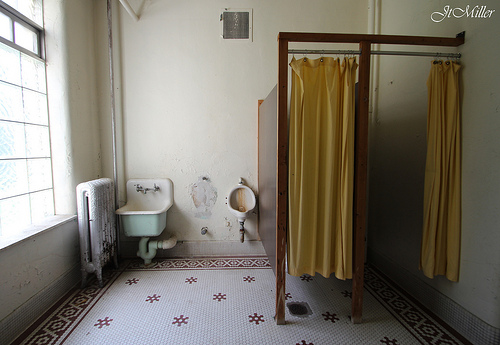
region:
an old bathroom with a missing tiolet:
[8, 10, 457, 330]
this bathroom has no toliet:
[92, 138, 298, 302]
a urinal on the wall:
[214, 168, 271, 258]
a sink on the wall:
[95, 153, 197, 272]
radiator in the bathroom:
[57, 168, 125, 276]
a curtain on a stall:
[272, 31, 439, 283]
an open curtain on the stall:
[368, 42, 473, 306]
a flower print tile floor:
[98, 259, 312, 342]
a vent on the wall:
[197, 5, 267, 42]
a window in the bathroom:
[5, 22, 84, 219]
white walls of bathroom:
[0, 1, 497, 338]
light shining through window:
[1, 1, 54, 236]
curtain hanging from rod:
[286, 47, 355, 278]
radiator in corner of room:
[75, 175, 117, 283]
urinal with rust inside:
[227, 176, 257, 243]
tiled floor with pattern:
[16, 254, 464, 343]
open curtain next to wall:
[418, 51, 461, 280]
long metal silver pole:
[104, 3, 119, 183]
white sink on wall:
[116, 178, 176, 237]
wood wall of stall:
[256, 84, 280, 272]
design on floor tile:
[166, 310, 198, 330]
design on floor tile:
[316, 309, 337, 329]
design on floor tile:
[245, 310, 269, 325]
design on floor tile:
[146, 293, 168, 315]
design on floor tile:
[99, 310, 119, 335]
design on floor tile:
[126, 276, 147, 295]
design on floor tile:
[188, 273, 205, 290]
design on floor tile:
[236, 264, 269, 292]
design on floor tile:
[292, 270, 312, 288]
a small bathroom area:
[0, 1, 498, 343]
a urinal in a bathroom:
[227, 177, 258, 241]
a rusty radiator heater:
[76, 175, 125, 290]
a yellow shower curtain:
[289, 55, 355, 288]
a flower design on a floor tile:
[171, 312, 189, 328]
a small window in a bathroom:
[0, 5, 48, 58]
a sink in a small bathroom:
[115, 176, 175, 262]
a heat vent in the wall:
[217, 8, 254, 44]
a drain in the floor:
[283, 298, 313, 321]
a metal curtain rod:
[286, 46, 462, 60]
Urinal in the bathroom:
[223, 165, 258, 251]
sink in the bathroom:
[123, 174, 169, 247]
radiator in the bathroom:
[66, 173, 126, 297]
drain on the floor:
[273, 288, 313, 331]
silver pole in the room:
[91, 23, 128, 243]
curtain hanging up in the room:
[294, 50, 358, 250]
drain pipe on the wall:
[135, 237, 169, 269]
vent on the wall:
[208, 0, 273, 57]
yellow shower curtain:
[416, 41, 480, 318]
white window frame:
[5, 30, 79, 251]